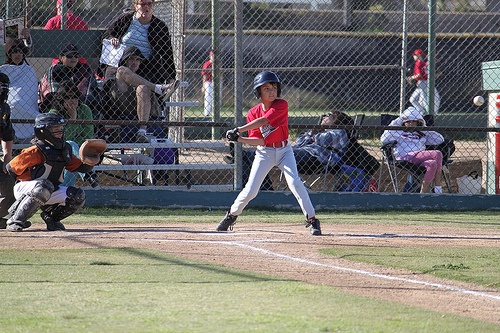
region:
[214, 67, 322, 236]
A red shirt batter boy with a blue helmet on.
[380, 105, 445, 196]
A girl sitting with pink pants on.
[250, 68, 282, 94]
A blue helmet on a batter.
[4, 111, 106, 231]
A catcher kneeling down.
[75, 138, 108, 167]
A brown glove on a catchers hand.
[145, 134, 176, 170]
A blue and white cooler behind the fence.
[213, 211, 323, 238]
Black cleats on a batter.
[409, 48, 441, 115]
Two players to the back right in red and white.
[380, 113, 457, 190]
A chair a girl in pink pants is sitting in.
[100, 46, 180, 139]
A man sitting past the fence on bleachers with his legs crossed.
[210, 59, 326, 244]
a boy swinging a bat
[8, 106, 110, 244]
a catcher behind home plate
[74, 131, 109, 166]
a brown catcher's mitt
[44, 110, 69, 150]
a catcher's mask on a face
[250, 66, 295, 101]
a helmet on a boy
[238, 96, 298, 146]
a red shirt on a boy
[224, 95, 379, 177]
a woman reclining behind a chain link fence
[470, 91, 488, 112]
a baseball in the air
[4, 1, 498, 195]
a chain link fence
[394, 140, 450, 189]
pink pants on a woman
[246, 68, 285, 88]
a black baseball helmet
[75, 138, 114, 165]
a brown baseball glove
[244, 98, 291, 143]
a red baseball jersey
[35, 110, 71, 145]
a catcher's helmet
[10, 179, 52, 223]
black leg protective gear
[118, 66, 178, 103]
the leg of a man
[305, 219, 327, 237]
the shoe of a boy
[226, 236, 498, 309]
a white line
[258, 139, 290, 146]
a red boy's belt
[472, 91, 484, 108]
a small white ball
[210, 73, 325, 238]
a boy playing baseball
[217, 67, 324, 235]
a boy about to swing his bat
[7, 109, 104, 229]
a catcher ready to catch the ball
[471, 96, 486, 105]
a white baseball in the air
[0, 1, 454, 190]
people watching the baseball game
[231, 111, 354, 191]
a lady sleeping in the background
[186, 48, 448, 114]
another baseball game in the background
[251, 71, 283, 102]
a black safety helmet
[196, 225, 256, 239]
a white home plate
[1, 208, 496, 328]
a baseball field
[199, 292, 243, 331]
part of some green grass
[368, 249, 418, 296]
part of a white line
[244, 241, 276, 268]
part of a ground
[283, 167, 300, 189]
edge of a trouser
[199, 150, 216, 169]
part of a fence